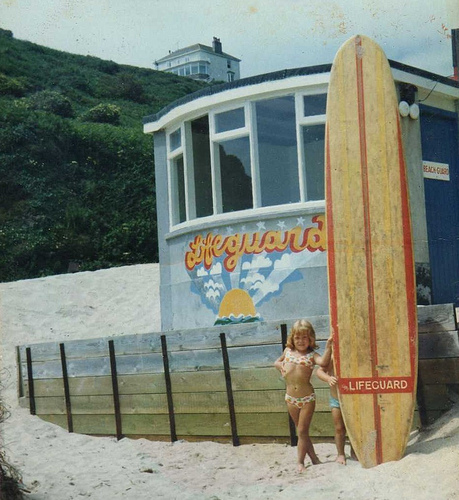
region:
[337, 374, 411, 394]
sign indicating lifeguard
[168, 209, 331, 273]
sign indicating lifeguard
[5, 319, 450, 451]
wood fence to establish boundaries between beach and shelter house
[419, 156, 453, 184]
wood sign indicating beach guard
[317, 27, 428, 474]
wood long board for surfing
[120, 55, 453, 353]
shelter house on sandy beach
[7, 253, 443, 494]
tan colored sand alongside beach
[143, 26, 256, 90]
beach house alongside ocean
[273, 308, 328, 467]
human girl with bikini on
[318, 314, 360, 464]
human boy partially hidden by surfboard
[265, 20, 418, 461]
small girl standing by board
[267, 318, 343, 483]
small girl standing in sand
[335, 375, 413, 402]
red lifeguard logo on board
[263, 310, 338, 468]
young girl wearing suit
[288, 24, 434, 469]
large surf board on beach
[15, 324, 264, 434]
wooden fence on beach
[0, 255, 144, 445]
hill of sand on beach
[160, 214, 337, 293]
life guard logo on building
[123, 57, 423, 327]
life guard shack on beach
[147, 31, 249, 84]
large house on top of hill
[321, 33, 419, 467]
A very tall surfboard beside a girl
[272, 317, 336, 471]
A small girl with blonde hair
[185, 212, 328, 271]
Lifeguard written in cursive letters on a building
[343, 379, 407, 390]
The word Lifeguard on a surfboard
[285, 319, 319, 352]
Blonde hair on a little girl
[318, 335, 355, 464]
A little boy behind a surfboard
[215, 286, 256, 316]
Half an orange sun on a building.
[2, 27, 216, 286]
A dark green grassy hillside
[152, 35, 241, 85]
A large white house on top of a hill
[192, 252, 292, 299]
Clouds under the word Lifeguard.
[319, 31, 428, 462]
tall wooden surf board in sand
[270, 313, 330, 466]
little girl beside a surfboard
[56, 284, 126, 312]
sand on the ground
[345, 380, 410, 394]
the words lifeguard on board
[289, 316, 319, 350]
face with blond hair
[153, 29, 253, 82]
house on top of a hill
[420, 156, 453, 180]
beach guard house on the beach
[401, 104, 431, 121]
lights on the side of beach guard house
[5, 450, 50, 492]
dead grass in sand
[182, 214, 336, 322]
lifeguard logo on the building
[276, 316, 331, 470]
A little girl in a bathing suit.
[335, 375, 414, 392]
The word lifeguard in white.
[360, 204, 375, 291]
Part of a red stripe on the surfboard.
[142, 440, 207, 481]
Part of the white sand.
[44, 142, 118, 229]
Part of the tree in the background.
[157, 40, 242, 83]
A house in the background.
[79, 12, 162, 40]
Part of the grey sky.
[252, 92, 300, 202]
A front window on the building.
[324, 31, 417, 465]
A tall surfboard.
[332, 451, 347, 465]
The foot of a boy.